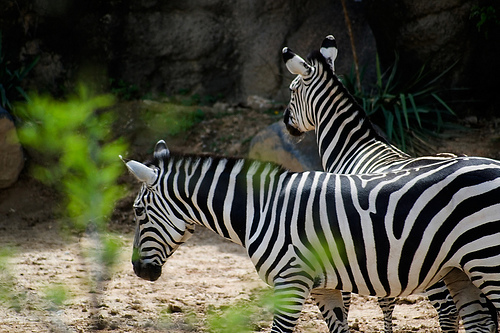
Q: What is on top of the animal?
A: Zebra's head.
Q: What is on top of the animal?
A: Zebra's head.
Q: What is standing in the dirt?
A: Two zebras.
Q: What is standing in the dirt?
A: Zebra standing tall.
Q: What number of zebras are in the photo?
A: 2.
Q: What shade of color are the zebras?
A: Black and white.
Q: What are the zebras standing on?
A: Dirt.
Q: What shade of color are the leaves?
A: Green.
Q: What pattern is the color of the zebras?
A: Stripes.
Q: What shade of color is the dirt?
A: Light brown.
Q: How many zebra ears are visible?
A: 4.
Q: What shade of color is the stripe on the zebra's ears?
A: Black.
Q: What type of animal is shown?
A: Zebras.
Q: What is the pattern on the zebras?
A: Stripes.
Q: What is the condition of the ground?
A: Bare.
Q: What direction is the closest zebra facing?
A: Left.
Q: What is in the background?
A: A rock wall.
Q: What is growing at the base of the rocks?
A: Grass.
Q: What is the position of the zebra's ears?
A: Raised.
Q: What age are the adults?
A: Adult.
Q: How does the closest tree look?
A: Blurry.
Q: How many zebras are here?
A: 2.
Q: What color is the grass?
A: Brown.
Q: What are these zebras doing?
A: Eating.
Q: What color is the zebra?
A: Black and white.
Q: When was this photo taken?
A: During the day.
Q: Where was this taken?
A: A safari.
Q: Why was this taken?
A: To show the zebras.